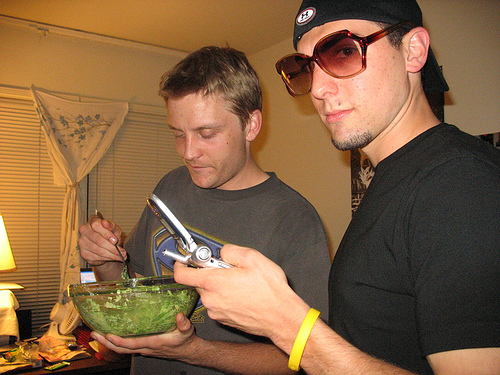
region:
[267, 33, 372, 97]
oversize tortoise shell glasses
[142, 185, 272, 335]
silver flip cellular phone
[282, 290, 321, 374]
man wearing yellow rubber bracelet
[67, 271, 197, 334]
glass bowl full of guacamole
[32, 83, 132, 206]
tied white curtain with blue flowers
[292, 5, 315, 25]
white embroidered logo with black print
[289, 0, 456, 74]
black baseball cap is backwards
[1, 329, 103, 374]
clutter on a dining room table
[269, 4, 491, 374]
young man in black clothing and oversized sunglasses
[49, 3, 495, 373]
two young men hanging out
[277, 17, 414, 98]
A brown pair of sunglasses.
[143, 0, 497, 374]
A man holding a cellphone in his hand.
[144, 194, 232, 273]
A silver flip cellphone.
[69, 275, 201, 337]
A glass bowl.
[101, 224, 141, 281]
An eating utensil.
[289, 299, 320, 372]
A yellow rubber wrist band.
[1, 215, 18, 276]
A lampshade.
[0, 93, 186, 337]
White colored blinds.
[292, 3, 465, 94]
A black ball cap on backwards.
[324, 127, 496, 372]
A black short sleeved shirt.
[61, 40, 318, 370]
a man with a bowl of green guacamole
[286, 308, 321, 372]
a yellow braclet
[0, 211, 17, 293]
a turned on lamp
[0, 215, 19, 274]
part of a white lamp shade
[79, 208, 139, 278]
a hand holding a spoon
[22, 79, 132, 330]
a white curtain with blue flowers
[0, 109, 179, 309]
white metal blinds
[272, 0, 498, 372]
a man in a black shirt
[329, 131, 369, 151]
black facial hair on a guy's chin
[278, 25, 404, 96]
a pair of brown sunglasses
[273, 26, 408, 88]
The sunglasses the guy is wearing.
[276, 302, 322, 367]
The yellow bracelet on the guy's wrist.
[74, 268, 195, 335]
The bowl in the guy's hand.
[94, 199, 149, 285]
The fork in the guy's hand.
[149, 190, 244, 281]
The phone in the guy's hand.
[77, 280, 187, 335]
The green food product in the bowl.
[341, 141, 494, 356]
The black t-shirt the guy is wearing.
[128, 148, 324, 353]
The gray t-shirt the guy is wearing.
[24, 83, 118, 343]
The white and blue curtain on the window.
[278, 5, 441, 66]
The black hat the guy is wearing.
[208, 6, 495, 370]
person wearing oversized sunglasses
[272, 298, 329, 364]
yellow band on person's wrist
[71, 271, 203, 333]
clear bowl with green dip in it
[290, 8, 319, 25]
white oval with black H on it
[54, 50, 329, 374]
man wearing gray superman shirt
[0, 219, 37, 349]
lamp on table in the background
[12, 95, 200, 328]
two windows in background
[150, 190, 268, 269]
silver flip phone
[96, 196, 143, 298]
spoon in bowl of green dip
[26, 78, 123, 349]
curtain hanging between two windows